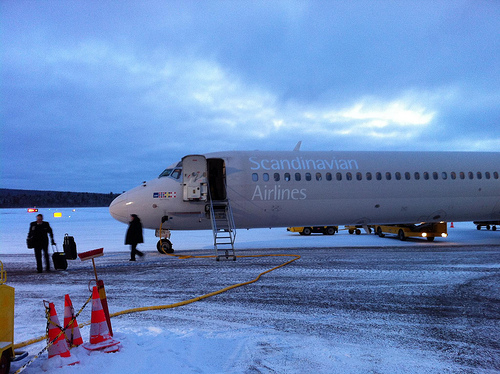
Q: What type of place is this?
A: It is an airport.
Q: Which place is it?
A: It is an airport.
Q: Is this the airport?
A: Yes, it is the airport.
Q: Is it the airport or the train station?
A: It is the airport.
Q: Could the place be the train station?
A: No, it is the airport.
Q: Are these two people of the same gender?
A: No, they are both male and female.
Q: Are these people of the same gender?
A: No, they are both male and female.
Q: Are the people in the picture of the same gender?
A: No, they are both male and female.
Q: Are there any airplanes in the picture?
A: Yes, there is an airplane.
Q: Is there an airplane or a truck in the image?
A: Yes, there is an airplane.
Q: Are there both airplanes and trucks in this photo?
A: Yes, there are both an airplane and a truck.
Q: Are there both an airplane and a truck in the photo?
A: Yes, there are both an airplane and a truck.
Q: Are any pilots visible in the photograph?
A: No, there are no pilots.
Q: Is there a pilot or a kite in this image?
A: No, there are no pilots or kites.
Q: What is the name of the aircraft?
A: The aircraft is an airplane.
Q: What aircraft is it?
A: The aircraft is an airplane.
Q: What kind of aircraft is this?
A: This is an airplane.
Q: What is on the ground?
A: The plane is on the ground.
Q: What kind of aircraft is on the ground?
A: The aircraft is an airplane.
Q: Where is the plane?
A: The plane is on the ground.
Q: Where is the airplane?
A: The plane is on the ground.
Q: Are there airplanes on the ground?
A: Yes, there is an airplane on the ground.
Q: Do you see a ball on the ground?
A: No, there is an airplane on the ground.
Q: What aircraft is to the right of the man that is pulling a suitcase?
A: The aircraft is an airplane.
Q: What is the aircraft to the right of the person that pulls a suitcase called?
A: The aircraft is an airplane.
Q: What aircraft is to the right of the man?
A: The aircraft is an airplane.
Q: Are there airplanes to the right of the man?
A: Yes, there is an airplane to the right of the man.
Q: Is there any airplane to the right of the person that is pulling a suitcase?
A: Yes, there is an airplane to the right of the man.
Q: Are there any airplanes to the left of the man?
A: No, the airplane is to the right of the man.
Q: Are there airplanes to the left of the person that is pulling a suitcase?
A: No, the airplane is to the right of the man.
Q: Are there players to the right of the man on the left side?
A: No, there is an airplane to the right of the man.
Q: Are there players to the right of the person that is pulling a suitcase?
A: No, there is an airplane to the right of the man.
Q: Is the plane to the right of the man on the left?
A: Yes, the plane is to the right of the man.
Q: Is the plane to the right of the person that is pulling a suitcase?
A: Yes, the plane is to the right of the man.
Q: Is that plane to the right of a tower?
A: No, the plane is to the right of the man.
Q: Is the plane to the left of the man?
A: No, the plane is to the right of the man.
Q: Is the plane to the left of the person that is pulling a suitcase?
A: No, the plane is to the right of the man.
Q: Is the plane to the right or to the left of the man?
A: The plane is to the right of the man.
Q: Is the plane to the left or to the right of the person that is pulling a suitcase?
A: The plane is to the right of the man.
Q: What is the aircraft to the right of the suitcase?
A: The aircraft is an airplane.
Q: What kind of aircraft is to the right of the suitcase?
A: The aircraft is an airplane.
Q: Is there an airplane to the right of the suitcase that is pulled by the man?
A: Yes, there is an airplane to the right of the suitcase.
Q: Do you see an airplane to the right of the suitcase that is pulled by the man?
A: Yes, there is an airplane to the right of the suitcase.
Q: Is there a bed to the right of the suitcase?
A: No, there is an airplane to the right of the suitcase.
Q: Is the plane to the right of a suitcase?
A: Yes, the plane is to the right of a suitcase.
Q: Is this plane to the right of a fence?
A: No, the plane is to the right of a suitcase.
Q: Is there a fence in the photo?
A: No, there are no fences.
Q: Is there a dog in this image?
A: No, there are no dogs.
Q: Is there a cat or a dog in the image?
A: No, there are no dogs or cats.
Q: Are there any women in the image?
A: Yes, there is a woman.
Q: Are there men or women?
A: Yes, there is a woman.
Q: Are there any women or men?
A: Yes, there is a woman.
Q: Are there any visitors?
A: No, there are no visitors.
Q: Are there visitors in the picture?
A: No, there are no visitors.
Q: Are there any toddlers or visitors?
A: No, there are no visitors or toddlers.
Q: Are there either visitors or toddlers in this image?
A: No, there are no visitors or toddlers.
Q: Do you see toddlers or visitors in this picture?
A: No, there are no visitors or toddlers.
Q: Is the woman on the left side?
A: Yes, the woman is on the left of the image.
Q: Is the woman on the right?
A: No, the woman is on the left of the image.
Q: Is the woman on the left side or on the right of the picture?
A: The woman is on the left of the image.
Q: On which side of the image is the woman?
A: The woman is on the left of the image.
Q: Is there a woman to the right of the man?
A: Yes, there is a woman to the right of the man.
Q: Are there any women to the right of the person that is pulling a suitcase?
A: Yes, there is a woman to the right of the man.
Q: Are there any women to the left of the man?
A: No, the woman is to the right of the man.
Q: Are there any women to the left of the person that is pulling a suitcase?
A: No, the woman is to the right of the man.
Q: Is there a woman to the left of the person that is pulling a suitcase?
A: No, the woman is to the right of the man.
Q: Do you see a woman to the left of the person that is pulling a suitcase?
A: No, the woman is to the right of the man.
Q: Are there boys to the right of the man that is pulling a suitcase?
A: No, there is a woman to the right of the man.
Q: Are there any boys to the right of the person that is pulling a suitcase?
A: No, there is a woman to the right of the man.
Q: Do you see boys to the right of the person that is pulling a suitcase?
A: No, there is a woman to the right of the man.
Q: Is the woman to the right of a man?
A: Yes, the woman is to the right of a man.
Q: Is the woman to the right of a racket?
A: No, the woman is to the right of a man.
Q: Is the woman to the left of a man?
A: No, the woman is to the right of a man.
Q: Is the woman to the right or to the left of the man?
A: The woman is to the right of the man.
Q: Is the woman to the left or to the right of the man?
A: The woman is to the right of the man.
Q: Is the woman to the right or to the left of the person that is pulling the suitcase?
A: The woman is to the right of the man.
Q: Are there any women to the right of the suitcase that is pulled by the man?
A: Yes, there is a woman to the right of the suitcase.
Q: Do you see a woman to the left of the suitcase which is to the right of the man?
A: No, the woman is to the right of the suitcase.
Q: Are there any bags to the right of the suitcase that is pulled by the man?
A: No, there is a woman to the right of the suitcase.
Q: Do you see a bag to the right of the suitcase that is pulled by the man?
A: No, there is a woman to the right of the suitcase.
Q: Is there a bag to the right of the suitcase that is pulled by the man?
A: No, there is a woman to the right of the suitcase.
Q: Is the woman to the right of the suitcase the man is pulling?
A: Yes, the woman is to the right of the suitcase.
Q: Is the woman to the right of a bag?
A: No, the woman is to the right of the suitcase.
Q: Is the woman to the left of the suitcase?
A: No, the woman is to the right of the suitcase.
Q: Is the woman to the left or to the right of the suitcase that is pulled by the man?
A: The woman is to the right of the suitcase.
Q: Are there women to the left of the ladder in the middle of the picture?
A: Yes, there is a woman to the left of the ladder.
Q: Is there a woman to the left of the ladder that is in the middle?
A: Yes, there is a woman to the left of the ladder.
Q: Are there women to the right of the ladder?
A: No, the woman is to the left of the ladder.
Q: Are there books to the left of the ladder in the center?
A: No, there is a woman to the left of the ladder.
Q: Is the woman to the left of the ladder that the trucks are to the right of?
A: Yes, the woman is to the left of the ladder.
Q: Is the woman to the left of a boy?
A: No, the woman is to the left of the ladder.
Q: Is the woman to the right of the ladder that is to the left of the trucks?
A: No, the woman is to the left of the ladder.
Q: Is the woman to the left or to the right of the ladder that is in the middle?
A: The woman is to the left of the ladder.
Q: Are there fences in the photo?
A: No, there are no fences.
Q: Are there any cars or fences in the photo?
A: No, there are no fences or cars.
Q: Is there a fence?
A: No, there are no fences.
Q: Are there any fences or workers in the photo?
A: No, there are no fences or workers.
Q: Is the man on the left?
A: Yes, the man is on the left of the image.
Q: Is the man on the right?
A: No, the man is on the left of the image.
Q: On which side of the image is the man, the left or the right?
A: The man is on the left of the image.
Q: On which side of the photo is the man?
A: The man is on the left of the image.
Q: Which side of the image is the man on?
A: The man is on the left of the image.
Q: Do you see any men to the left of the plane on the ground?
A: Yes, there is a man to the left of the plane.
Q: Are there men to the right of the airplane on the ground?
A: No, the man is to the left of the airplane.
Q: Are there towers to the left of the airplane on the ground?
A: No, there is a man to the left of the plane.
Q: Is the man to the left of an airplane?
A: Yes, the man is to the left of an airplane.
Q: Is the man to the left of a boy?
A: No, the man is to the left of an airplane.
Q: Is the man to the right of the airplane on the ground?
A: No, the man is to the left of the airplane.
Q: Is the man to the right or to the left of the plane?
A: The man is to the left of the plane.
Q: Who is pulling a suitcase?
A: The man is pulling a suitcase.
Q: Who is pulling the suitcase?
A: The man is pulling a suitcase.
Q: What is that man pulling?
A: The man is pulling a suitcase.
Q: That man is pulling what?
A: The man is pulling a suitcase.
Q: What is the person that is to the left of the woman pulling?
A: The man is pulling a suitcase.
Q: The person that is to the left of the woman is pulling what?
A: The man is pulling a suitcase.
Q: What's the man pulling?
A: The man is pulling a suitcase.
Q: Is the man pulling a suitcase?
A: Yes, the man is pulling a suitcase.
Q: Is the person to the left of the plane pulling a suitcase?
A: Yes, the man is pulling a suitcase.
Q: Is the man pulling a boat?
A: No, the man is pulling a suitcase.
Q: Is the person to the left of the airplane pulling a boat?
A: No, the man is pulling a suitcase.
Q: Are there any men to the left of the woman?
A: Yes, there is a man to the left of the woman.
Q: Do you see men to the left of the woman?
A: Yes, there is a man to the left of the woman.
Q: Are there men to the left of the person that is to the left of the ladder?
A: Yes, there is a man to the left of the woman.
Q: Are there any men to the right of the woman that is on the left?
A: No, the man is to the left of the woman.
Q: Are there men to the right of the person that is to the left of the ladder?
A: No, the man is to the left of the woman.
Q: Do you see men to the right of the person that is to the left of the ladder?
A: No, the man is to the left of the woman.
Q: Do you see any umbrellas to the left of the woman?
A: No, there is a man to the left of the woman.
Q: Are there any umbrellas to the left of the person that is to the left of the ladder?
A: No, there is a man to the left of the woman.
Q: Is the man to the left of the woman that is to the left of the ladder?
A: Yes, the man is to the left of the woman.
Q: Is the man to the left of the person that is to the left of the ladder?
A: Yes, the man is to the left of the woman.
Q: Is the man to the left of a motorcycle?
A: No, the man is to the left of the woman.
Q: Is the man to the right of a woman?
A: No, the man is to the left of a woman.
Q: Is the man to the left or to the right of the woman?
A: The man is to the left of the woman.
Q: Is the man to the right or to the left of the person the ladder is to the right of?
A: The man is to the left of the woman.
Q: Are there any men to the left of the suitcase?
A: Yes, there is a man to the left of the suitcase.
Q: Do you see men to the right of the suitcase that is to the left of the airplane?
A: No, the man is to the left of the suitcase.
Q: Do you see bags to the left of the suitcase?
A: No, there is a man to the left of the suitcase.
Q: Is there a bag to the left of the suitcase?
A: No, there is a man to the left of the suitcase.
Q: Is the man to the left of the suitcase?
A: Yes, the man is to the left of the suitcase.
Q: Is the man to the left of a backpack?
A: No, the man is to the left of the suitcase.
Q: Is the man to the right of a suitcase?
A: No, the man is to the left of a suitcase.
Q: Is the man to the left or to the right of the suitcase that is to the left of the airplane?
A: The man is to the left of the suitcase.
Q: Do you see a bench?
A: No, there are no benches.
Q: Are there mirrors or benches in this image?
A: No, there are no benches or mirrors.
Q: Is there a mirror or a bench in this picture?
A: No, there are no benches or mirrors.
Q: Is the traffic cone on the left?
A: Yes, the traffic cone is on the left of the image.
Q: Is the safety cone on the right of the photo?
A: No, the safety cone is on the left of the image.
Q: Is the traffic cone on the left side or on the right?
A: The traffic cone is on the left of the image.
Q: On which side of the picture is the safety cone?
A: The safety cone is on the left of the image.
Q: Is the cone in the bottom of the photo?
A: Yes, the cone is in the bottom of the image.